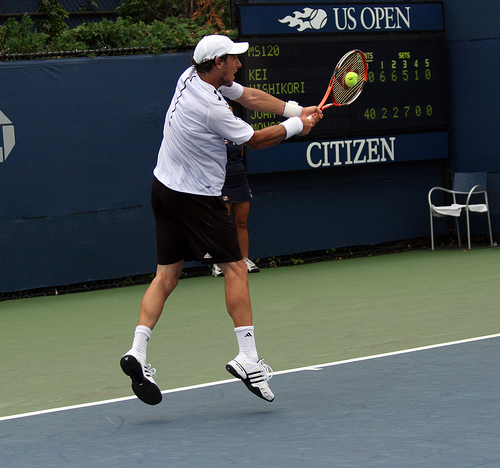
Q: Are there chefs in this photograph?
A: No, there are no chefs.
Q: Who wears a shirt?
A: The player wears a shirt.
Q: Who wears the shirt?
A: The player wears a shirt.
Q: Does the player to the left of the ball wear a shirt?
A: Yes, the player wears a shirt.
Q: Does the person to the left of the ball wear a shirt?
A: Yes, the player wears a shirt.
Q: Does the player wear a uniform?
A: No, the player wears a shirt.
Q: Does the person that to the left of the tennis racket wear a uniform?
A: No, the player wears a shirt.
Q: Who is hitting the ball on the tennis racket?
A: The player is hitting the ball.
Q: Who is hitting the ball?
A: The player is hitting the ball.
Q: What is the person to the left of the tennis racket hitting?
A: The player is hitting the ball.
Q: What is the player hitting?
A: The player is hitting the ball.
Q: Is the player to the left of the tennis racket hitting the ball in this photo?
A: Yes, the player is hitting the ball.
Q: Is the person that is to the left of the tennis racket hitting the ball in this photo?
A: Yes, the player is hitting the ball.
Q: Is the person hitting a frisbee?
A: No, the player is hitting the ball.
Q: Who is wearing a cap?
A: The player is wearing a cap.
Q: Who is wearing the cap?
A: The player is wearing a cap.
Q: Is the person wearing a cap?
A: Yes, the player is wearing a cap.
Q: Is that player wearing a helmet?
A: No, the player is wearing a cap.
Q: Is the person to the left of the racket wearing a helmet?
A: No, the player is wearing a cap.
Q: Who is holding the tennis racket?
A: The player is holding the tennis racket.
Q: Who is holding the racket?
A: The player is holding the tennis racket.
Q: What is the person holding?
A: The player is holding the tennis racket.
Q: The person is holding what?
A: The player is holding the tennis racket.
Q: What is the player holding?
A: The player is holding the tennis racket.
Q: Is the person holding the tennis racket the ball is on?
A: Yes, the player is holding the racket.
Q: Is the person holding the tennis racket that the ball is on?
A: Yes, the player is holding the racket.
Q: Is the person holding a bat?
A: No, the player is holding the racket.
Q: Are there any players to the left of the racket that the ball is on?
A: Yes, there is a player to the left of the tennis racket.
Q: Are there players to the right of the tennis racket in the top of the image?
A: No, the player is to the left of the racket.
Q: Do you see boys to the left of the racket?
A: No, there is a player to the left of the racket.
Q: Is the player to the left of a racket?
A: Yes, the player is to the left of a racket.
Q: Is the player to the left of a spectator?
A: No, the player is to the left of a racket.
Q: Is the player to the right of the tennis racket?
A: No, the player is to the left of the tennis racket.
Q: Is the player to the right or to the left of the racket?
A: The player is to the left of the racket.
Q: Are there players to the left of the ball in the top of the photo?
A: Yes, there is a player to the left of the ball.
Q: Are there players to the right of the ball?
A: No, the player is to the left of the ball.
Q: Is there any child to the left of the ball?
A: No, there is a player to the left of the ball.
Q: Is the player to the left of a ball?
A: Yes, the player is to the left of a ball.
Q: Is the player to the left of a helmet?
A: No, the player is to the left of a ball.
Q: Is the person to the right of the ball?
A: No, the player is to the left of the ball.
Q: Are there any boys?
A: No, there are no boys.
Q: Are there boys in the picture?
A: No, there are no boys.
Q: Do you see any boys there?
A: No, there are no boys.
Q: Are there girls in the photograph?
A: No, there are no girls.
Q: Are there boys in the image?
A: No, there are no boys.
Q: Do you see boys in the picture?
A: No, there are no boys.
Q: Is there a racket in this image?
A: Yes, there is a racket.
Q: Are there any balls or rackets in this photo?
A: Yes, there is a racket.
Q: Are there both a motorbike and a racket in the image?
A: No, there is a racket but no motorcycles.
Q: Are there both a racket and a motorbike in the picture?
A: No, there is a racket but no motorcycles.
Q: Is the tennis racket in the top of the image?
A: Yes, the tennis racket is in the top of the image.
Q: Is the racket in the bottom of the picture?
A: No, the racket is in the top of the image.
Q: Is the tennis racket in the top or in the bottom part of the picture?
A: The tennis racket is in the top of the image.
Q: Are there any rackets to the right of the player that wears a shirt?
A: Yes, there is a racket to the right of the player.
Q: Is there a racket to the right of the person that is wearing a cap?
A: Yes, there is a racket to the right of the player.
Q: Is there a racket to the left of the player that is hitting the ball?
A: No, the racket is to the right of the player.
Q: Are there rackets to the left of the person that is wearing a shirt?
A: No, the racket is to the right of the player.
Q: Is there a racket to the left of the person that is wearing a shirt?
A: No, the racket is to the right of the player.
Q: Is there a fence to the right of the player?
A: No, there is a racket to the right of the player.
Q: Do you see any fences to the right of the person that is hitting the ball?
A: No, there is a racket to the right of the player.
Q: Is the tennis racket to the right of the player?
A: Yes, the tennis racket is to the right of the player.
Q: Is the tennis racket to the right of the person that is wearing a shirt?
A: Yes, the tennis racket is to the right of the player.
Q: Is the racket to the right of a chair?
A: No, the racket is to the right of the player.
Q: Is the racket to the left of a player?
A: No, the racket is to the right of a player.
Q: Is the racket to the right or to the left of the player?
A: The racket is to the right of the player.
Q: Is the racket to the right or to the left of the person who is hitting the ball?
A: The racket is to the right of the player.